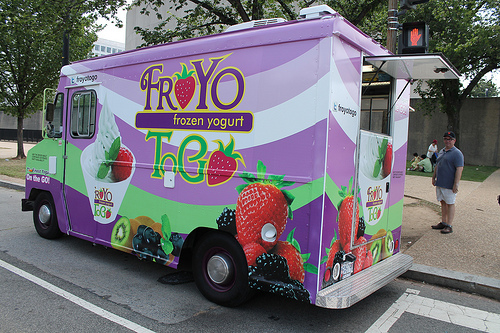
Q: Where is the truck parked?
A: The street.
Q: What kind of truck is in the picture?
A: Food truck.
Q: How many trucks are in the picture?
A: One.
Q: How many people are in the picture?
A: 4.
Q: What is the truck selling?
A: Frozen yogurt.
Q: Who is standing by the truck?
A: A man.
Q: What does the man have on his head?
A: A hat.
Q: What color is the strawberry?
A: Red.